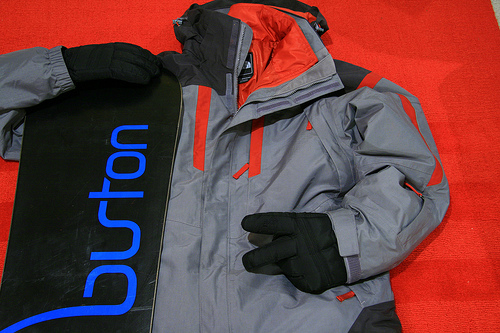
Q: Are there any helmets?
A: No, there are no helmets.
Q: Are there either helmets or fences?
A: No, there are no helmets or fences.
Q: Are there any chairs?
A: No, there are no chairs.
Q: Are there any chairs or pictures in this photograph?
A: No, there are no chairs or pictures.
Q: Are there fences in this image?
A: No, there are no fences.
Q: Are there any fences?
A: No, there are no fences.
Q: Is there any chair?
A: No, there are no chairs.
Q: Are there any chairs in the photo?
A: No, there are no chairs.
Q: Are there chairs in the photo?
A: No, there are no chairs.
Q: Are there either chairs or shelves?
A: No, there are no chairs or shelves.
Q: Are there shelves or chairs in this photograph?
A: No, there are no chairs or shelves.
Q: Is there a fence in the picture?
A: No, there are no fences.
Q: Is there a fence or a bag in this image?
A: No, there are no fences or bags.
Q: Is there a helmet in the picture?
A: No, there are no helmets.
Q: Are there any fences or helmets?
A: No, there are no helmets or fences.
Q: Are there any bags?
A: No, there are no bags.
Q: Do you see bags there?
A: No, there are no bags.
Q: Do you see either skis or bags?
A: No, there are no bags or skis.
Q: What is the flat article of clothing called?
A: The clothing item is a jacket.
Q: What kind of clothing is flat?
A: The clothing is a jacket.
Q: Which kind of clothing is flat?
A: The clothing is a jacket.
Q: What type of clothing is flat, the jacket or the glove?
A: The jacket is flat.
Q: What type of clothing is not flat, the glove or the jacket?
A: The glove is not flat.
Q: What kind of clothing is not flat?
A: The clothing is a glove.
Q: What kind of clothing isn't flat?
A: The clothing is a glove.